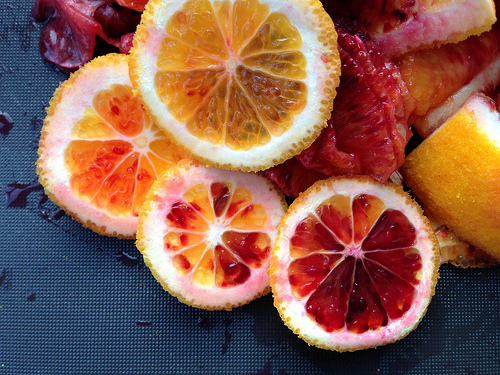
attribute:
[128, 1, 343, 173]
lemon — cut, slice, yellow, red, half, part, sliced, slices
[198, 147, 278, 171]
peel — yellow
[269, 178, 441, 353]
orange — sliced, stained, red, maroon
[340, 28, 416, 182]
fruit — other, peeling, wrinkled, chopped, display, sliced, thin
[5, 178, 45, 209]
juice — fruit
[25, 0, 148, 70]
strawerries — slice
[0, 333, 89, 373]
cloth — texture, blue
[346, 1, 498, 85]
pomegranets — picture, messy, fresh, peeled, purple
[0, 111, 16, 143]
drop — water